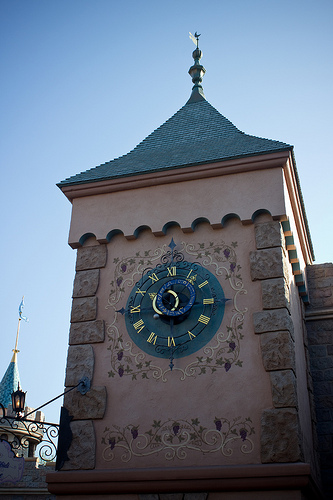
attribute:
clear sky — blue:
[0, 0, 332, 467]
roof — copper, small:
[57, 87, 315, 264]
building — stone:
[53, 171, 307, 424]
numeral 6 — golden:
[165, 333, 175, 349]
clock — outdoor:
[133, 283, 211, 343]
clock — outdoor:
[124, 261, 225, 359]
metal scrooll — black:
[0, 402, 61, 471]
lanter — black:
[5, 378, 30, 422]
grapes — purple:
[215, 418, 248, 441]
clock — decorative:
[131, 264, 203, 330]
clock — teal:
[114, 236, 234, 370]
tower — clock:
[40, 75, 308, 482]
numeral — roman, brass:
[163, 260, 178, 281]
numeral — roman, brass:
[184, 262, 194, 288]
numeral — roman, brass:
[197, 274, 209, 293]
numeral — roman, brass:
[185, 306, 211, 329]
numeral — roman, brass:
[159, 328, 179, 349]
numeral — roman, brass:
[121, 301, 144, 319]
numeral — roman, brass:
[143, 270, 161, 290]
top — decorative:
[183, 25, 210, 88]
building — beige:
[44, 14, 332, 497]